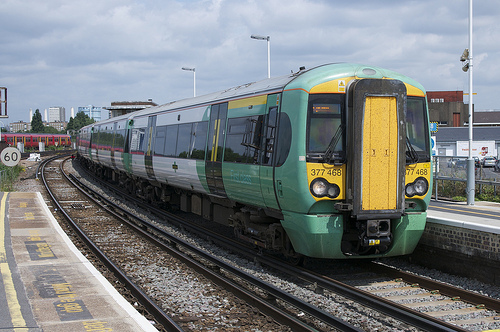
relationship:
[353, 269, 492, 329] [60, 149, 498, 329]
gravel on tracks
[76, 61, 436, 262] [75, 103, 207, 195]
train has stripes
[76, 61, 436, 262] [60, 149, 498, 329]
train on tracks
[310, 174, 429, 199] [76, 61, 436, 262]
lights are on train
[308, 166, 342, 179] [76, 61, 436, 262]
numbers are on train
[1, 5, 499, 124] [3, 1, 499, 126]
clouds are in sky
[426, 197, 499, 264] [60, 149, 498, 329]
platform next to tracks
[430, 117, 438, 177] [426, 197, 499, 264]
sign next to platform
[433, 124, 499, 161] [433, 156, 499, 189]
building next to a parking lot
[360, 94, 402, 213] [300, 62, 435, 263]
door on train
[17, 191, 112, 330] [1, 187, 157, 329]
writing on platform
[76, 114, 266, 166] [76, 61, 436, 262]
windows on train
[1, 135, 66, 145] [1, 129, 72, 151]
windows on train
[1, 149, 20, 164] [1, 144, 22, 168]
number on sign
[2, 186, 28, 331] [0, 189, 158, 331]
line on sidewalk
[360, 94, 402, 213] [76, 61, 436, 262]
door on train